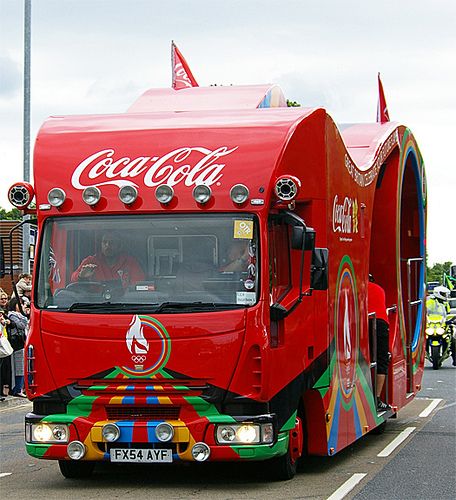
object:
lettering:
[72, 144, 238, 190]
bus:
[8, 49, 428, 479]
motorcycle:
[424, 297, 453, 370]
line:
[323, 468, 362, 498]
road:
[327, 359, 456, 478]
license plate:
[110, 445, 174, 463]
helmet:
[433, 284, 448, 291]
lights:
[228, 184, 251, 204]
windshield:
[35, 210, 259, 306]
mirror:
[310, 245, 330, 292]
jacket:
[69, 252, 145, 290]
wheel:
[271, 397, 304, 481]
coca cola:
[71, 148, 239, 192]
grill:
[105, 404, 179, 417]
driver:
[70, 227, 146, 289]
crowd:
[0, 271, 34, 399]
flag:
[171, 43, 205, 89]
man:
[424, 284, 451, 322]